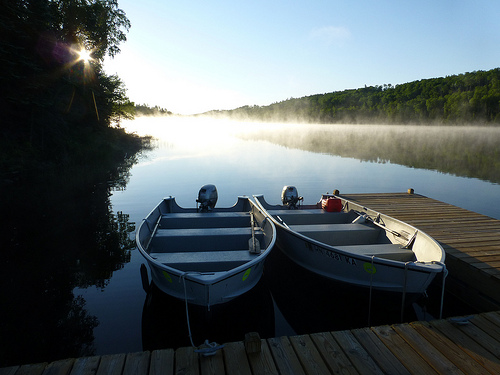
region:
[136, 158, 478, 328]
two boats on the deck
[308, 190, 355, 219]
a red gas tank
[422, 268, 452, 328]
a rope hanging from boat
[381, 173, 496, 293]
a wooden pier on water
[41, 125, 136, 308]
tree shadows on the water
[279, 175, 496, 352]
a boat in the watera boat in the water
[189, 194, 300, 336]
a small boat in water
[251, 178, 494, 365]
a small boat in water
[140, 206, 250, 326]
a boat tied up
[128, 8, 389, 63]
a sky that is blue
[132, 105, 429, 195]
a body of water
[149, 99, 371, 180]
a body of calm water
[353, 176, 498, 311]
a wooden dock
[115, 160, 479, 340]
two boats next to each other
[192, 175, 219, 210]
motor on the boat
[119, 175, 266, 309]
the boat is white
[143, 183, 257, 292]
seats in the boat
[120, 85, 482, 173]
mist on the water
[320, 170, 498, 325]
deck next to boats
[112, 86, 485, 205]
the water is green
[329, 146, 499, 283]
the deck is brown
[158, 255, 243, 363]
rope for the boat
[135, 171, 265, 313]
boat in dock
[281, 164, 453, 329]
boat in dock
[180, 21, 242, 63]
white clouds in blue sky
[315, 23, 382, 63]
white clouds in blue sky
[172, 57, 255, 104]
white clouds in blue sky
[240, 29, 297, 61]
white clouds in blue sky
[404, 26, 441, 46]
white clouds in blue sky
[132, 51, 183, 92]
white clouds in blue sky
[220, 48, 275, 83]
white clouds in blue sky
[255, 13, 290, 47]
white clouds in blue sky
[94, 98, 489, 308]
Water is still in the morning at sunrise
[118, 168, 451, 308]
2 boats are moored at the dock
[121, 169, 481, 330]
2 identical boats are next to each other in the water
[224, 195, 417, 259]
Boats have paddles in them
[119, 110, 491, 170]
White steam is coming up over the lake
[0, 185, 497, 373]
Dock is made with boards of wood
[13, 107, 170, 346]
Shadows of trees are seen in the water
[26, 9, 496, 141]
Blue sky is clear and sunny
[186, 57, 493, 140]
Large trees line the edge of the water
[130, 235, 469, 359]
ropes hang over the boat near the dock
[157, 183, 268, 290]
boat in water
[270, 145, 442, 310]
boat docked at pier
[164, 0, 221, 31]
white clouds in blue sky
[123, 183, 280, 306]
boat floating in water near dock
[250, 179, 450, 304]
boat anchored near dock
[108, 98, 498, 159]
mist floating above water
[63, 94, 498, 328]
body of water beyond dock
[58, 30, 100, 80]
sunlight through tree leaves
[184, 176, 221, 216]
motor on rear of boat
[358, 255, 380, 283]
yellow circle on boat front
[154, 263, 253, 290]
two yellow circles on boat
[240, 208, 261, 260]
silver oar in boat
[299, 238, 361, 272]
boat identification numbers in black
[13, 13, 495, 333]
a scene during the day time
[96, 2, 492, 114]
a blue sky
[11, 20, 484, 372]
a scene of a dock